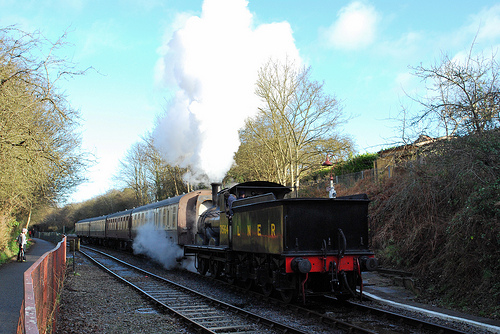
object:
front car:
[190, 171, 367, 297]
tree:
[1, 25, 101, 257]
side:
[1, 231, 68, 332]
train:
[76, 152, 375, 299]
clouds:
[404, 6, 498, 66]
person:
[12, 225, 33, 265]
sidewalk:
[0, 236, 54, 332]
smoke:
[125, 213, 195, 275]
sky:
[1, 37, 453, 178]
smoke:
[127, 11, 309, 188]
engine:
[174, 160, 222, 268]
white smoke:
[167, 102, 272, 199]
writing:
[215, 219, 280, 239]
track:
[79, 248, 497, 332]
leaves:
[0, 23, 87, 230]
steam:
[160, 1, 291, 195]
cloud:
[322, 0, 379, 62]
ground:
[63, 293, 491, 330]